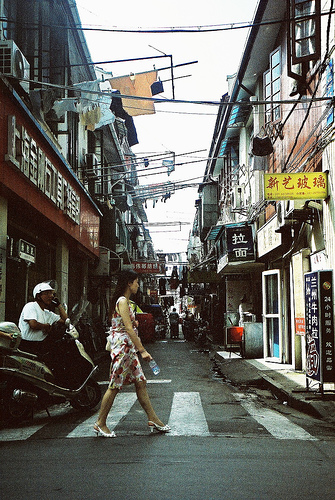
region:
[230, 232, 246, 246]
white foreign character on sign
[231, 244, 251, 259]
white foreign character on sign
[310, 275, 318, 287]
white foreign character on sign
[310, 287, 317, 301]
white foreign character on sign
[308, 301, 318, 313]
white foreign character on sign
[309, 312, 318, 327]
white foreign character on sign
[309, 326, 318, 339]
white foreign character on sign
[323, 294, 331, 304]
white foreign character on sign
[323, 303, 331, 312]
white foreign character on sign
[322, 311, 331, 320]
white foreign character on sign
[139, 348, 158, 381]
a woman holding a water bottle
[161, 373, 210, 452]
a white line painted on the pavement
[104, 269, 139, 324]
a woman with black hair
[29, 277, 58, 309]
a man wearing a white helmet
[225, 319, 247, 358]
a orange chair on a sidewalk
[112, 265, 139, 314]
a woman with long hair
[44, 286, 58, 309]
a man using a cell phone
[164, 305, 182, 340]
a woman in a alley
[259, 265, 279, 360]
a glass door that is open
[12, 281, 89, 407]
a man sitting on a scooter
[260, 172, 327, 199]
Yellow sign with Chinese writing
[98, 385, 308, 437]
Crosswalk in the street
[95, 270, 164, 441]
Woman walking across the street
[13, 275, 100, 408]
Man on a motorcycle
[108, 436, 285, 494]
Grey concrete street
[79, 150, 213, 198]
Clotheslines across street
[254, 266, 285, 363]
Open glass door on sidewalk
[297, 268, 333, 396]
Black bus stop on sidewalk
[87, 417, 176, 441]
White dress shoes on woman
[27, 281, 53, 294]
White helmet on man's head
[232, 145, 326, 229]
Sign on the building.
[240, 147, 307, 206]
Red words on the sign.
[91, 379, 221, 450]
White shoes on the woman.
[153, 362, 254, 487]
White lines on the road.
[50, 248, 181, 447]
Woman crossing the street.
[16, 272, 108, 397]
Man with a white helmet.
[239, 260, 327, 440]
Doors on the building.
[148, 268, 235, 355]
people in the background.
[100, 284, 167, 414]
Woman with a water bottle.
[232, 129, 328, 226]
Sign on the building.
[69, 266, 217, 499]
Woman on the street.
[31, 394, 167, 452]
Heels on the woman.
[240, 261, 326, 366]
Door on the building.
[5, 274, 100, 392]
Man with a helmet.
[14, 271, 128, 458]
Man on a motor bike.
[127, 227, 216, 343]
People in the background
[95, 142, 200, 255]
Poles over the street.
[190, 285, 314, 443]
Curb on the road.